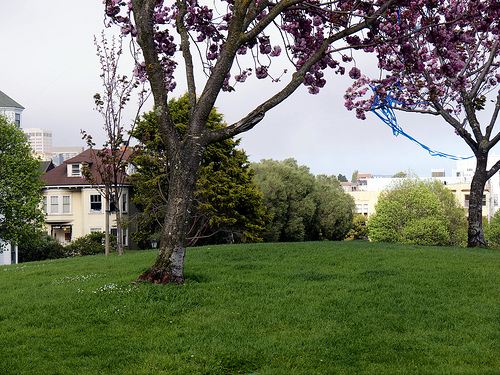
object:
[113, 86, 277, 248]
tree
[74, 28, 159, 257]
tree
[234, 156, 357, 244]
trees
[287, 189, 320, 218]
green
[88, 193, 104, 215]
window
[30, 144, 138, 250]
building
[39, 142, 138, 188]
roof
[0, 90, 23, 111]
roof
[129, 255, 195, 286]
base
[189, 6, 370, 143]
branch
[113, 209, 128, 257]
post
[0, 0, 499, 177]
sky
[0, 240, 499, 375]
ground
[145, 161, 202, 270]
stem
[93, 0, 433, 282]
tree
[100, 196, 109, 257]
post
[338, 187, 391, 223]
building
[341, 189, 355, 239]
edge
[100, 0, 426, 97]
blossoms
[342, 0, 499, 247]
tree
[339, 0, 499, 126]
blossoms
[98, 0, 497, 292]
two trees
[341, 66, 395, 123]
purple flowers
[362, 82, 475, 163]
blue kite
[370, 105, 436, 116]
tree limbs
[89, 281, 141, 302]
white flowers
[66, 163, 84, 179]
window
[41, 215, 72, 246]
back porch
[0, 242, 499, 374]
green lawn